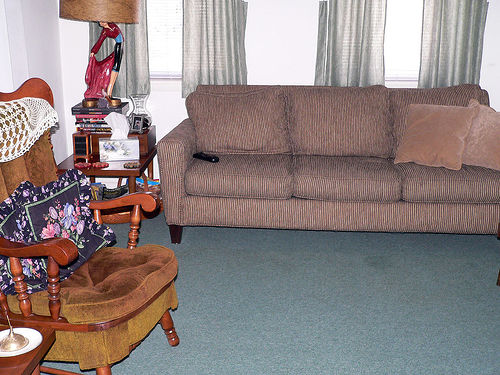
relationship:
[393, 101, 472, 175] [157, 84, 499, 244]
pillows on sofa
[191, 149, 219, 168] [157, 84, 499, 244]
remote on sofa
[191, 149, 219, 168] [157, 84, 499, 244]
remote control on couch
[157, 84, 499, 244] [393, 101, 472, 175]
couch has a throw pillow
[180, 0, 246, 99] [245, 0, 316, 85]
drapes on windows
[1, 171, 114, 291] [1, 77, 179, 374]
pillows on chair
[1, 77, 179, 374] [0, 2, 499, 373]
chair in living room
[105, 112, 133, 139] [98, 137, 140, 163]
facial tissue in a box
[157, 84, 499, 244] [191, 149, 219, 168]
couch has a remote control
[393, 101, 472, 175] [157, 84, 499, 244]
pillows on couch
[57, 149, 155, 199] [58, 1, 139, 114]
table has a lamp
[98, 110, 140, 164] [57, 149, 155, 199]
tissues on table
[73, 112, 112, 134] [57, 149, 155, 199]
books on table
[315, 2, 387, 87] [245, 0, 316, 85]
curtains on windows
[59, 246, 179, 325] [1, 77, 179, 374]
cushion on chair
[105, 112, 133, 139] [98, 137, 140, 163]
tissue in a box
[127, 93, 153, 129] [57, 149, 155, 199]
vase on table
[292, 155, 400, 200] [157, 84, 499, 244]
cushion on couch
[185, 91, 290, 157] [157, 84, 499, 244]
back cushion on sofa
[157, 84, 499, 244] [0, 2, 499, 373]
couch in living room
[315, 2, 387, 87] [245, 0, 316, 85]
curtain on window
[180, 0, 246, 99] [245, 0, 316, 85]
drapes on window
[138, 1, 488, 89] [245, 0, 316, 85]
drapes on windows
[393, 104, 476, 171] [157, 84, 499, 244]
pillows on sofa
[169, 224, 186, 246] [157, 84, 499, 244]
leg of sofa